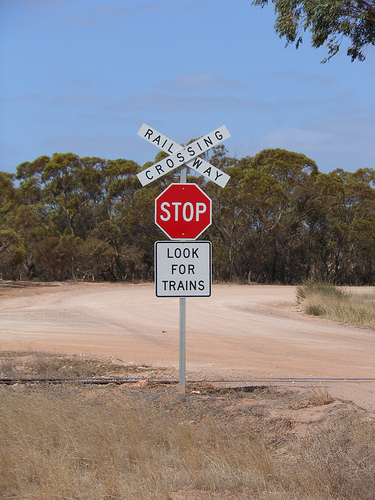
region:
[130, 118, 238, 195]
a railway crossing traffic sign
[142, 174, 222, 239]
a stop sign on a post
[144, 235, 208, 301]
a black and white sign on a post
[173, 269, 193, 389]
a long and grey sign post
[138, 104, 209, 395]
a bunch of signs on a grey post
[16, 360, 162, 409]
a bunch of empty train tracks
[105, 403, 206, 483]
a bunch of dead brown grass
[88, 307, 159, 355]
a big patch of brown dirt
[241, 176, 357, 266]
a bunch of dark green trees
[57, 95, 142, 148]
the blue sky at dusk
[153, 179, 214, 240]
The sign is red AND WHITE.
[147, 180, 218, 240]
The sign is octagonal.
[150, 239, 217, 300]
The sign is black and white.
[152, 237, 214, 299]
The sign is square.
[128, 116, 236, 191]
The sign indicates there's a railroad crossing.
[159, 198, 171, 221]
The letter is white.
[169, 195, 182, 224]
The letter is white.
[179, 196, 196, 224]
The letter is white.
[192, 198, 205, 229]
The letter is white.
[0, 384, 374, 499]
The grass is brown and overgrown.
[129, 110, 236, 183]
this is sign on the road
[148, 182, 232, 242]
this is a line on the road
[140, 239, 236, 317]
this is a line on the road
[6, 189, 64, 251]
this is a tree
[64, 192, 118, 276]
this is a tree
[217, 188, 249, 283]
this is a tree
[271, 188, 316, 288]
this is a tree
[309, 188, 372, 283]
this is a tree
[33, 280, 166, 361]
this is a road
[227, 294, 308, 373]
this is a road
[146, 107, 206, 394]
a pole with many stop signs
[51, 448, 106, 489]
a bunch of dead dry grass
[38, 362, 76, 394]
an empty railroad track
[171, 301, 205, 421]
a long grey pole for sign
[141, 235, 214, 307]
a black and white sign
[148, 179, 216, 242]
a big red stop sign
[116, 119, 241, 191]
the black and white railroad sign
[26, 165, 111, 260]
a bunch of green trees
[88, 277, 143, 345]
a big patch of brown dirt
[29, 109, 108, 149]
a clear and blue sky